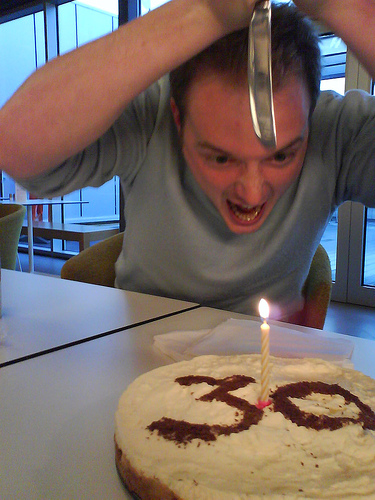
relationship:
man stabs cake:
[0, 0, 375, 321] [126, 322, 354, 487]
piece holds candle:
[255, 399, 273, 407] [260, 321, 270, 400]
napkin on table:
[154, 316, 355, 367] [0, 265, 373, 495]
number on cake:
[147, 366, 373, 447] [121, 352, 348, 482]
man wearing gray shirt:
[0, 0, 375, 321] [15, 70, 375, 328]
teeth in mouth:
[228, 198, 262, 222] [224, 194, 269, 226]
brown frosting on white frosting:
[206, 377, 371, 432] [225, 351, 326, 361]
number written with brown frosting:
[147, 366, 373, 447] [206, 377, 371, 432]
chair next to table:
[59, 228, 332, 329] [0, 265, 373, 495]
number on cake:
[147, 370, 374, 447] [107, 350, 374, 497]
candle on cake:
[256, 296, 273, 409] [98, 290, 336, 498]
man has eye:
[117, 9, 361, 331] [189, 133, 237, 176]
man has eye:
[0, 0, 375, 321] [267, 152, 287, 164]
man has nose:
[0, 0, 375, 321] [233, 172, 280, 205]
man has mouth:
[0, 0, 375, 321] [213, 183, 281, 264]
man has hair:
[0, 0, 375, 321] [168, 3, 321, 132]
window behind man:
[55, 0, 121, 254] [0, 0, 375, 321]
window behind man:
[0, 8, 51, 251] [0, 0, 375, 321]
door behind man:
[316, 31, 374, 308] [0, 0, 375, 321]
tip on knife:
[255, 130, 279, 150] [242, 0, 280, 154]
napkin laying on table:
[154, 316, 355, 367] [0, 270, 332, 499]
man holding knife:
[0, 0, 375, 321] [248, 5, 282, 149]